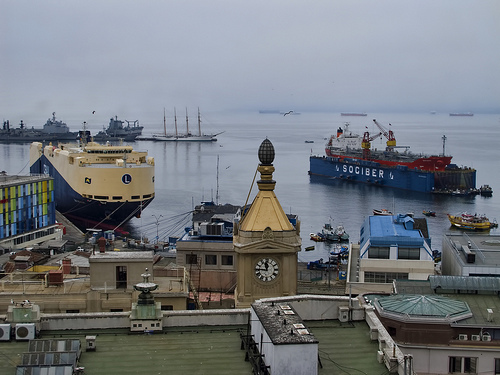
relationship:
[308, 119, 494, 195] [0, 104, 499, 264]
boat on water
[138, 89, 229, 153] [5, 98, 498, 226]
boat on ocean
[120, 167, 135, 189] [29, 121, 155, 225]
blue logo on front of a boat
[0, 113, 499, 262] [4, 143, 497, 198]
ocean of ocean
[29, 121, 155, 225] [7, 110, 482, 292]
boat docked at pier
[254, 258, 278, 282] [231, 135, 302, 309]
clock on building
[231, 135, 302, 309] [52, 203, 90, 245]
building on pier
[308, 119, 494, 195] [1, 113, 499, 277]
boat in water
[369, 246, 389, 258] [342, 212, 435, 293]
window on building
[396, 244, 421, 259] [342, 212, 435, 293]
window on building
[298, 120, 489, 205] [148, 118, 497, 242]
boat in water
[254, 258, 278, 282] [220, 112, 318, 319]
clock on a building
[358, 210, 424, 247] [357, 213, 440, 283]
blue roof on a building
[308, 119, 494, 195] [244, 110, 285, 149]
boat in a row on water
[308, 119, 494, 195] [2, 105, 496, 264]
boat in ocean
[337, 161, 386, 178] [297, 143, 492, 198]
letters painted on boat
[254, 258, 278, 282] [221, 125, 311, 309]
clock on building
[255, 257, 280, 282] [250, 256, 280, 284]
clock has face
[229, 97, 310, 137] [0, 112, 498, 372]
bird flying over port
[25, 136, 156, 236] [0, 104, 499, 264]
boat in water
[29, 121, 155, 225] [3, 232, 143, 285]
boat tied to dock